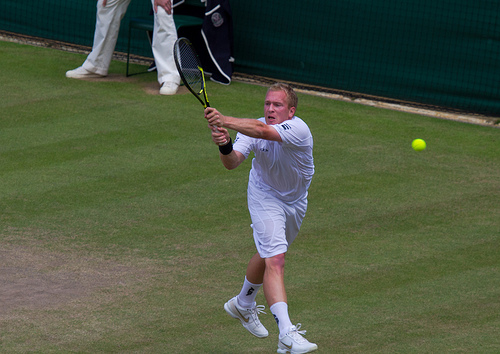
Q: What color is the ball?
A: Green.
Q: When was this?
A: Daytime.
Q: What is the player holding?
A: Raquet.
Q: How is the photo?
A: Clear.